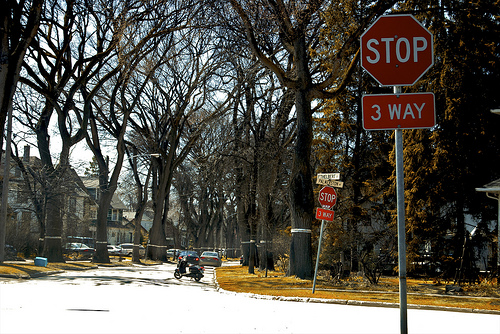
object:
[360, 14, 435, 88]
stop sign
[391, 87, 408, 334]
post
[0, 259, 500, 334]
road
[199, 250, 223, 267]
cars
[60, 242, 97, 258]
cars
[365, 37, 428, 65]
text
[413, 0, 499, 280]
trees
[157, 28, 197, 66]
branches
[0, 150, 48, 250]
houses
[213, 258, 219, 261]
tail lights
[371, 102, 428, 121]
3 way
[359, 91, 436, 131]
sign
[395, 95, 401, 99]
bolt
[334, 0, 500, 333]
right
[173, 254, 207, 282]
motorcycle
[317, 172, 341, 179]
street sign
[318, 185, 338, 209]
stop sign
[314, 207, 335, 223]
sign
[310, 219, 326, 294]
pole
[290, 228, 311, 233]
band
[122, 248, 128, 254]
mailbox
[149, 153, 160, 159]
street light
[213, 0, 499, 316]
either side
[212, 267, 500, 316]
curb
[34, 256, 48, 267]
box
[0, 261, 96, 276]
grass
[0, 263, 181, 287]
shadow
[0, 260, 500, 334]
ground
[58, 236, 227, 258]
driveway